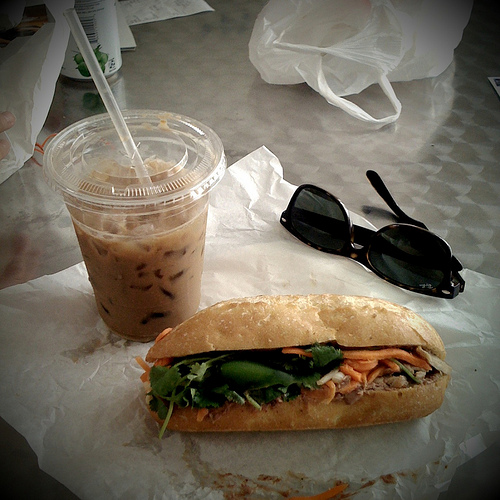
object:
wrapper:
[10, 145, 497, 498]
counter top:
[6, 4, 500, 497]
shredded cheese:
[368, 365, 432, 391]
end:
[135, 319, 257, 436]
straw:
[61, 8, 159, 209]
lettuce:
[145, 345, 345, 438]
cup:
[45, 107, 229, 346]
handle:
[274, 7, 373, 56]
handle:
[300, 52, 400, 129]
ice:
[134, 255, 200, 316]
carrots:
[322, 342, 433, 393]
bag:
[244, 3, 475, 131]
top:
[0, 8, 497, 495]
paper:
[0, 146, 500, 499]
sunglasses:
[280, 170, 467, 300]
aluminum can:
[60, 0, 122, 79]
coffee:
[72, 155, 208, 339]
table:
[8, 4, 498, 498]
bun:
[133, 286, 450, 435]